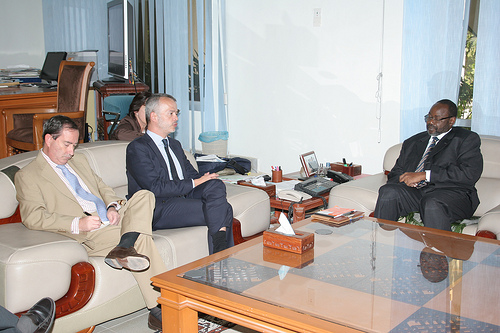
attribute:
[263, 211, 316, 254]
box — tissues , brown, orange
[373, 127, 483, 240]
suit — black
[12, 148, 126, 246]
jacket — brown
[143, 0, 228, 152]
blinds — blue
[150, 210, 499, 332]
square — large 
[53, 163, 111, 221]
tie — blue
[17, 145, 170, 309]
suit — beige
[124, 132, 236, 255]
suit — gray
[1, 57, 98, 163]
chair — wooden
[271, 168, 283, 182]
pot — brown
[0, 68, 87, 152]
desk — wood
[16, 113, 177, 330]
man — writing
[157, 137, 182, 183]
tie — black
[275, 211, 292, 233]
tissue — white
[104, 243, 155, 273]
shoe — brown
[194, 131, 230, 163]
trash can — small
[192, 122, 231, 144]
garbage bag — blue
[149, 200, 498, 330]
coffee table — large , square 